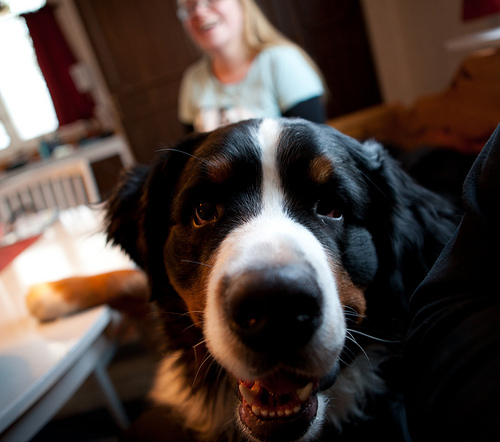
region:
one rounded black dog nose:
[225, 261, 328, 356]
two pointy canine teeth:
[231, 372, 318, 405]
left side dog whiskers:
[342, 301, 394, 378]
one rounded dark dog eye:
[193, 195, 223, 230]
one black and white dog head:
[117, 103, 445, 440]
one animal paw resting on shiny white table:
[25, 265, 142, 326]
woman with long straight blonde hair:
[171, 4, 289, 59]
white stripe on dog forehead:
[249, 116, 297, 211]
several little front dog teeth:
[247, 402, 303, 416]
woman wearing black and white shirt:
[166, 0, 332, 127]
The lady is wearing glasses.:
[171, 6, 246, 29]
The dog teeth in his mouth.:
[222, 379, 307, 409]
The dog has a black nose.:
[233, 276, 325, 326]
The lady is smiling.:
[178, 2, 280, 47]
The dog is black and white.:
[135, 118, 414, 415]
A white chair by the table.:
[19, 158, 107, 210]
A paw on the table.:
[8, 255, 85, 321]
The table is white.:
[14, 303, 85, 366]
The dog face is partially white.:
[216, 225, 354, 371]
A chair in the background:
[368, 80, 492, 139]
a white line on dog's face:
[177, 100, 362, 340]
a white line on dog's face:
[198, 86, 328, 277]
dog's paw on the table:
[7, 251, 129, 342]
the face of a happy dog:
[95, 114, 463, 436]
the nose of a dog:
[220, 259, 325, 363]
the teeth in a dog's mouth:
[233, 379, 318, 421]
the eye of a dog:
[312, 187, 353, 224]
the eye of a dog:
[183, 191, 228, 230]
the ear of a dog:
[364, 131, 469, 313]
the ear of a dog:
[97, 155, 167, 315]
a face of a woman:
[175, 1, 238, 55]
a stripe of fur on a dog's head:
[249, 119, 289, 216]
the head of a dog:
[95, 117, 466, 438]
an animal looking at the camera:
[85, 103, 480, 438]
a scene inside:
[0, 0, 495, 441]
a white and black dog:
[86, 85, 464, 440]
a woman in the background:
[156, 0, 350, 155]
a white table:
[2, 181, 200, 441]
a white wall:
[372, 3, 499, 115]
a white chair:
[0, 133, 104, 241]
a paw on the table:
[16, 225, 177, 342]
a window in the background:
[2, 2, 74, 156]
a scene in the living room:
[2, 0, 499, 428]